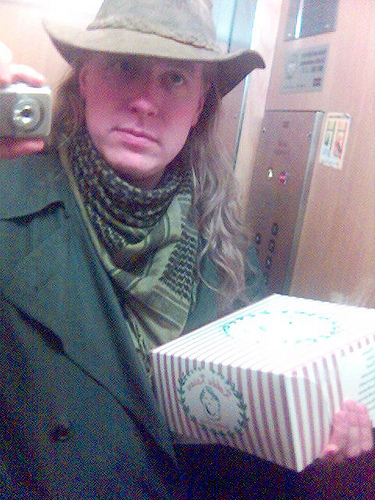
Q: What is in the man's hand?
A: A cake box.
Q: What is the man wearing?
A: A gray hat.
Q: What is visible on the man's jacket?
A: A button.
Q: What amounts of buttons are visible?
A: One.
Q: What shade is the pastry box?
A: Red, white and green.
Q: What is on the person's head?
A: Hat.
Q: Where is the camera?
A: Man's right hand.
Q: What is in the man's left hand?
A: Pastry box.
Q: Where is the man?
A: Elevator.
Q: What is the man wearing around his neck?
A: Scarf.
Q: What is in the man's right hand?
A: Silver camera.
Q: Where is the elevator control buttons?
A: By the man's left shoulder.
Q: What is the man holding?
A: A box.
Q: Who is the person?
A: A man.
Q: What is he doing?
A: Snapping photos.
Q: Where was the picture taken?
A: Elevator.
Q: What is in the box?
A: Food.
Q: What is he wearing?
A: Coat.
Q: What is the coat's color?
A: Green.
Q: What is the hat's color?
A: Brown.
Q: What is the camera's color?
A: Gray.